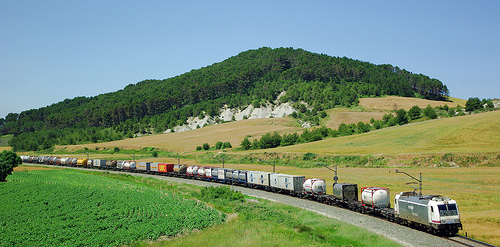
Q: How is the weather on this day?
A: It is clear.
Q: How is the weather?
A: It is clear.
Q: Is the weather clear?
A: Yes, it is clear.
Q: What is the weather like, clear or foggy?
A: It is clear.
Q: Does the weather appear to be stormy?
A: No, it is clear.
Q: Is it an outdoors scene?
A: Yes, it is outdoors.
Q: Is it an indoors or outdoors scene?
A: It is outdoors.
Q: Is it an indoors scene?
A: No, it is outdoors.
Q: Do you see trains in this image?
A: Yes, there is a train.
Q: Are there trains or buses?
A: Yes, there is a train.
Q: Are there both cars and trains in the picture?
A: Yes, there are both a train and a car.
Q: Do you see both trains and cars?
A: Yes, there are both a train and a car.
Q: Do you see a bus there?
A: No, there are no buses.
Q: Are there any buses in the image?
A: No, there are no buses.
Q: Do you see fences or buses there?
A: No, there are no buses or fences.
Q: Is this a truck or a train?
A: This is a train.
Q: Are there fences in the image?
A: No, there are no fences.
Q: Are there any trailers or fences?
A: No, there are no fences or trailers.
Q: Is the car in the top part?
A: No, the car is in the bottom of the image.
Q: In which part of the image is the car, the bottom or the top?
A: The car is in the bottom of the image.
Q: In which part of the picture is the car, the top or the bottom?
A: The car is in the bottom of the image.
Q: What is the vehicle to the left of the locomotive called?
A: The vehicle is a car.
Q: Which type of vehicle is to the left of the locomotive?
A: The vehicle is a car.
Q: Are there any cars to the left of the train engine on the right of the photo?
A: Yes, there is a car to the left of the train engine.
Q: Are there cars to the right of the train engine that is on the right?
A: No, the car is to the left of the engine.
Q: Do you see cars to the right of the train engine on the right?
A: No, the car is to the left of the engine.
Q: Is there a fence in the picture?
A: No, there are no fences.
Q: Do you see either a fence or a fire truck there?
A: No, there are no fences or fire trucks.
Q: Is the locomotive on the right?
A: Yes, the locomotive is on the right of the image.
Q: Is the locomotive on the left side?
A: No, the locomotive is on the right of the image.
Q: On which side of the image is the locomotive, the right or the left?
A: The locomotive is on the right of the image.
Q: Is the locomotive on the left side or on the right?
A: The locomotive is on the right of the image.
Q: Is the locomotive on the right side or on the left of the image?
A: The locomotive is on the right of the image.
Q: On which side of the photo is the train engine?
A: The train engine is on the right of the image.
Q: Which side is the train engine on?
A: The train engine is on the right of the image.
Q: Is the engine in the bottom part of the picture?
A: Yes, the engine is in the bottom of the image.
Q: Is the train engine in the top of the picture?
A: No, the train engine is in the bottom of the image.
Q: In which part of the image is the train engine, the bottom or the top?
A: The train engine is in the bottom of the image.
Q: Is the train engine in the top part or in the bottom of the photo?
A: The train engine is in the bottom of the image.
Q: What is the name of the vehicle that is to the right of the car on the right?
A: The vehicle is a locomotive.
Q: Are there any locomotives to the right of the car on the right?
A: Yes, there is a locomotive to the right of the car.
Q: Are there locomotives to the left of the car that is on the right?
A: No, the locomotive is to the right of the car.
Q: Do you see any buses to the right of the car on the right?
A: No, there is a locomotive to the right of the car.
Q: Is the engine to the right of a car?
A: Yes, the engine is to the right of a car.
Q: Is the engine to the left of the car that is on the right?
A: No, the engine is to the right of the car.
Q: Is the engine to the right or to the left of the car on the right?
A: The engine is to the right of the car.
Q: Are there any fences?
A: No, there are no fences.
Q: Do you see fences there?
A: No, there are no fences.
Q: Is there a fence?
A: No, there are no fences.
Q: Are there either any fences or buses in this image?
A: No, there are no fences or buses.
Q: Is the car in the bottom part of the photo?
A: Yes, the car is in the bottom of the image.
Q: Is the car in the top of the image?
A: No, the car is in the bottom of the image.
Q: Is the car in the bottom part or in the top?
A: The car is in the bottom of the image.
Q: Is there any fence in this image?
A: No, there are no fences.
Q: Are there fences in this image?
A: No, there are no fences.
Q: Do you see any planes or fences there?
A: No, there are no fences or planes.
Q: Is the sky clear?
A: Yes, the sky is clear.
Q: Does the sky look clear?
A: Yes, the sky is clear.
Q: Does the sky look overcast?
A: No, the sky is clear.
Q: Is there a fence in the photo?
A: No, there are no fences.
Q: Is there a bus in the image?
A: No, there are no buses.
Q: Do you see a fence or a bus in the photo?
A: No, there are no buses or fences.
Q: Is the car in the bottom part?
A: Yes, the car is in the bottom of the image.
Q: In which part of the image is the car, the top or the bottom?
A: The car is in the bottom of the image.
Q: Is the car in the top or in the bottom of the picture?
A: The car is in the bottom of the image.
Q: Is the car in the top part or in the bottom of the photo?
A: The car is in the bottom of the image.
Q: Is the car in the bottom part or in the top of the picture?
A: The car is in the bottom of the image.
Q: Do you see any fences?
A: No, there are no fences.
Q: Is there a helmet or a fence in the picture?
A: No, there are no fences or helmets.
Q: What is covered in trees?
A: The hill is covered in trees.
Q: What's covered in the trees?
A: The hill is covered in trees.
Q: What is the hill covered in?
A: The hill is covered in trees.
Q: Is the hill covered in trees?
A: Yes, the hill is covered in trees.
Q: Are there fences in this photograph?
A: No, there are no fences.